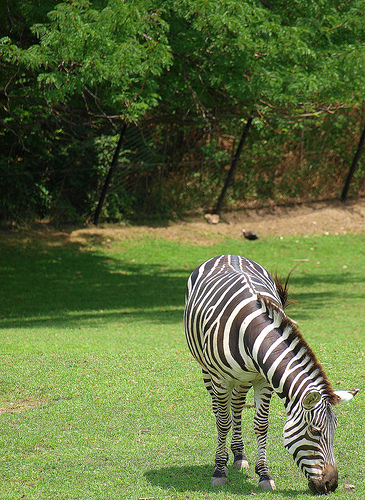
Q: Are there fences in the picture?
A: Yes, there is a fence.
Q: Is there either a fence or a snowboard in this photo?
A: Yes, there is a fence.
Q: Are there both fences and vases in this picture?
A: No, there is a fence but no vases.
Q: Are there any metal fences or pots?
A: Yes, there is a metal fence.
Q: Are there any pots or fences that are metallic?
A: Yes, the fence is metallic.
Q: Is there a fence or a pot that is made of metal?
A: Yes, the fence is made of metal.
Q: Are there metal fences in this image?
A: Yes, there is a metal fence.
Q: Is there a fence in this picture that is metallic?
A: Yes, there is a fence that is metallic.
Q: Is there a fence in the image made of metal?
A: Yes, there is a fence that is made of metal.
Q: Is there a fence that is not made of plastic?
A: Yes, there is a fence that is made of metal.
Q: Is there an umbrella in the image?
A: No, there are no umbrellas.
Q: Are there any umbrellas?
A: No, there are no umbrellas.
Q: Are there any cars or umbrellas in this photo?
A: No, there are no umbrellas or cars.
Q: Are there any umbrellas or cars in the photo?
A: No, there are no umbrellas or cars.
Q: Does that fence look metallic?
A: Yes, the fence is metallic.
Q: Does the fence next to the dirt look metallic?
A: Yes, the fence is metallic.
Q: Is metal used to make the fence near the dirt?
A: Yes, the fence is made of metal.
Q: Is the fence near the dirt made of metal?
A: Yes, the fence is made of metal.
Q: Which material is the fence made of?
A: The fence is made of metal.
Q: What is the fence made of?
A: The fence is made of metal.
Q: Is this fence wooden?
A: No, the fence is metallic.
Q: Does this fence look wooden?
A: No, the fence is metallic.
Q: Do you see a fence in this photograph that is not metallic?
A: No, there is a fence but it is metallic.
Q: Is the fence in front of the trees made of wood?
A: No, the fence is made of metal.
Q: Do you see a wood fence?
A: No, there is a fence but it is made of metal.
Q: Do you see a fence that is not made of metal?
A: No, there is a fence but it is made of metal.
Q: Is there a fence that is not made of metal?
A: No, there is a fence but it is made of metal.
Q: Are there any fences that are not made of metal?
A: No, there is a fence but it is made of metal.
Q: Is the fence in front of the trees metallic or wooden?
A: The fence is metallic.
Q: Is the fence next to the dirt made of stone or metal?
A: The fence is made of metal.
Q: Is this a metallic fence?
A: Yes, this is a metallic fence.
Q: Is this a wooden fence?
A: No, this is a metallic fence.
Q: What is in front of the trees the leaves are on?
A: The fence is in front of the trees.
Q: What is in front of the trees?
A: The fence is in front of the trees.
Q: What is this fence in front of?
A: The fence is in front of the trees.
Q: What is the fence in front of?
A: The fence is in front of the trees.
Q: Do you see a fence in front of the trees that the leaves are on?
A: Yes, there is a fence in front of the trees.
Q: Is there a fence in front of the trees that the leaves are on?
A: Yes, there is a fence in front of the trees.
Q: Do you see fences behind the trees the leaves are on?
A: No, the fence is in front of the trees.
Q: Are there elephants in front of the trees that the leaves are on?
A: No, there is a fence in front of the trees.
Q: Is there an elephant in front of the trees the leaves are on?
A: No, there is a fence in front of the trees.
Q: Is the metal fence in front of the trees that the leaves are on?
A: Yes, the fence is in front of the trees.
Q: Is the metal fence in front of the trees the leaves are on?
A: Yes, the fence is in front of the trees.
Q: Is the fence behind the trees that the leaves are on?
A: No, the fence is in front of the trees.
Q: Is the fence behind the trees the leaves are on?
A: No, the fence is in front of the trees.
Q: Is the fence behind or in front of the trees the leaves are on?
A: The fence is in front of the trees.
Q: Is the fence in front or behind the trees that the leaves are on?
A: The fence is in front of the trees.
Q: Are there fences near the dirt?
A: Yes, there is a fence near the dirt.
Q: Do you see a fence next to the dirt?
A: Yes, there is a fence next to the dirt.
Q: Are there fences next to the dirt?
A: Yes, there is a fence next to the dirt.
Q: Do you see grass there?
A: Yes, there is grass.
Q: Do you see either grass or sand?
A: Yes, there is grass.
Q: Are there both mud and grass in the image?
A: No, there is grass but no mud.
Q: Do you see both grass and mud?
A: No, there is grass but no mud.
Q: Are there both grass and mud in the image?
A: No, there is grass but no mud.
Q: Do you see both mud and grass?
A: No, there is grass but no mud.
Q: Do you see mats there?
A: No, there are no mats.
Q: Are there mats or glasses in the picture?
A: No, there are no mats or glasses.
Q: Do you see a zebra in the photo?
A: Yes, there is a zebra.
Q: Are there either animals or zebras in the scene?
A: Yes, there is a zebra.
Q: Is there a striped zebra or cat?
A: Yes, there is a striped zebra.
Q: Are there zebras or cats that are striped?
A: Yes, the zebra is striped.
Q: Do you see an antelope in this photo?
A: No, there are no antelopes.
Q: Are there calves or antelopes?
A: No, there are no antelopes or calves.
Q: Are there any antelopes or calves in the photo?
A: No, there are no antelopes or calves.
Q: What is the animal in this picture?
A: The animal is a zebra.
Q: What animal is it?
A: The animal is a zebra.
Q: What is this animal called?
A: This is a zebra.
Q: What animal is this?
A: This is a zebra.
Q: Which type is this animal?
A: This is a zebra.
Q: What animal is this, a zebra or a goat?
A: This is a zebra.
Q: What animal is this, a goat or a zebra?
A: This is a zebra.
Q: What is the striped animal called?
A: The animal is a zebra.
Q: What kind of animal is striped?
A: The animal is a zebra.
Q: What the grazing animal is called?
A: The animal is a zebra.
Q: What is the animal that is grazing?
A: The animal is a zebra.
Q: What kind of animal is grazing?
A: The animal is a zebra.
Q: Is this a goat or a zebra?
A: This is a zebra.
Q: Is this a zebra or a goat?
A: This is a zebra.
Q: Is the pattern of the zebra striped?
A: Yes, the zebra is striped.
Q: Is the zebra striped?
A: Yes, the zebra is striped.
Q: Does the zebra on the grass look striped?
A: Yes, the zebra is striped.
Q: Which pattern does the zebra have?
A: The zebra has striped pattern.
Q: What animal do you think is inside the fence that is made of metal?
A: The zebra is inside the fence.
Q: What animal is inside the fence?
A: The zebra is inside the fence.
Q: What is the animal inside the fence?
A: The animal is a zebra.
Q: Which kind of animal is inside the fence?
A: The animal is a zebra.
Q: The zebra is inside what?
A: The zebra is inside the fence.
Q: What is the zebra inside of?
A: The zebra is inside the fence.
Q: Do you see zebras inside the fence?
A: Yes, there is a zebra inside the fence.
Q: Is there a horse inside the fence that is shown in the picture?
A: No, there is a zebra inside the fence.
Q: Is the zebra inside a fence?
A: Yes, the zebra is inside a fence.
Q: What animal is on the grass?
A: The zebra is on the grass.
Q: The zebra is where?
A: The zebra is on the grass.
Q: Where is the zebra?
A: The zebra is on the grass.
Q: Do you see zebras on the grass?
A: Yes, there is a zebra on the grass.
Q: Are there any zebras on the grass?
A: Yes, there is a zebra on the grass.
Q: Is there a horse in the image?
A: No, there are no horses.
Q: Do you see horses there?
A: No, there are no horses.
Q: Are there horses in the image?
A: No, there are no horses.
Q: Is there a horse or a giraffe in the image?
A: No, there are no horses or giraffes.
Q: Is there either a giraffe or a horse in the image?
A: No, there are no horses or giraffes.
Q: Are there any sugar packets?
A: No, there are no sugar packets.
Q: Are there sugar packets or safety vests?
A: No, there are no sugar packets or safety vests.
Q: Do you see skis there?
A: No, there are no skis.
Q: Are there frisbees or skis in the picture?
A: No, there are no skis or frisbees.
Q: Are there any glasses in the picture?
A: No, there are no glasses.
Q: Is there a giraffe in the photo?
A: No, there are no giraffes.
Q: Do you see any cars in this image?
A: No, there are no cars.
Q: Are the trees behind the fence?
A: Yes, the trees are behind the fence.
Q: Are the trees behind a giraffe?
A: No, the trees are behind the fence.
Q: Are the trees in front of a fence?
A: No, the trees are behind a fence.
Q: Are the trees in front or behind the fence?
A: The trees are behind the fence.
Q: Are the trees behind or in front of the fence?
A: The trees are behind the fence.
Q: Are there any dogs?
A: No, there are no dogs.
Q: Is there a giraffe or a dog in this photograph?
A: No, there are no dogs or giraffes.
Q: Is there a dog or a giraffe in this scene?
A: No, there are no dogs or giraffes.